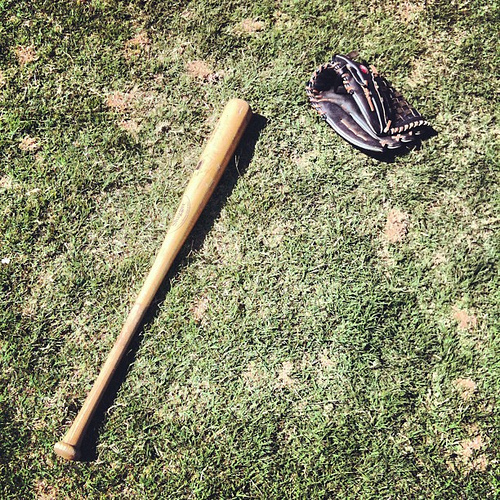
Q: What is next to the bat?
A: A baseball glove.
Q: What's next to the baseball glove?
A: A baseball bat.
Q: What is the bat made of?
A: Wood.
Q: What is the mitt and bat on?
A: The grass.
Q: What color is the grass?
A: Green.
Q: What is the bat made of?
A: Wood.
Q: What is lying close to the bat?
A: Ball glove.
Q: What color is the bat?
A: Brown.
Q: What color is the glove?
A: Dark brown.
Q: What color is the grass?
A: Green.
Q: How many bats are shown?
A: 1.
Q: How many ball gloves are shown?
A: 1.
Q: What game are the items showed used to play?
A: Baseball.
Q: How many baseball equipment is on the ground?
A: 2.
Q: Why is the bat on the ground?
A: A boy left it there.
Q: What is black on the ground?
A: Baseball glove.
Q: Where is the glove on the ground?
A: Beside the bat.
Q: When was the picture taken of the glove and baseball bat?
A: Afternoon.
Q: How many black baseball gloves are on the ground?
A: 1.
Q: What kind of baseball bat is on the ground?
A: Wooden.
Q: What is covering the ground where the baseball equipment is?
A: Green grass.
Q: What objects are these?
A: Bat and glove.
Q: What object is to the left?
A: Bat.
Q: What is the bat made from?
A: Wood.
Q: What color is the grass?
A: Green.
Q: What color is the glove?
A: Black.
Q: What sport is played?
A: Baseball.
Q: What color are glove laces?
A: Tan.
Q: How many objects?
A: Two.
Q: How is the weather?
A: Sunny.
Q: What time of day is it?
A: Daytime.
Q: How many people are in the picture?
A: None.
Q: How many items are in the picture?
A: Two.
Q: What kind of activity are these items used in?
A: Sports.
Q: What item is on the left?
A: Baseball bat.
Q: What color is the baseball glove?
A: Black.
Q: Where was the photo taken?
A: On the grass.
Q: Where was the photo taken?
A: Baseball field.